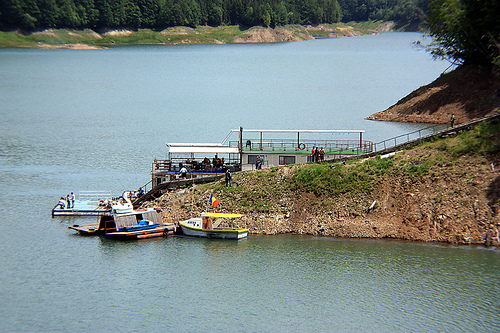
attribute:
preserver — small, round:
[188, 111, 496, 193]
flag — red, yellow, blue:
[192, 194, 225, 209]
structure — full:
[163, 142, 240, 169]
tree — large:
[415, 29, 499, 119]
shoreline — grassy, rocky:
[143, 158, 499, 249]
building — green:
[238, 144, 370, 170]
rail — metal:
[227, 139, 376, 155]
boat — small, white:
[96, 186, 131, 217]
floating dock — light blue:
[37, 185, 89, 233]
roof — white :
[170, 141, 236, 154]